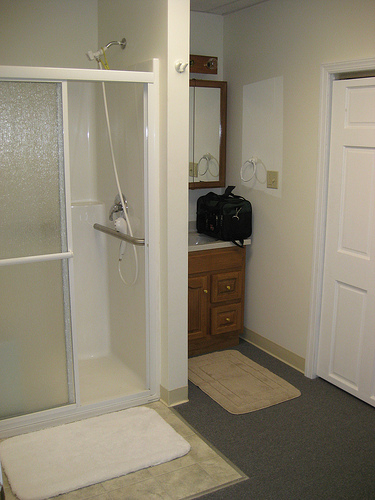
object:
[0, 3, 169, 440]
shower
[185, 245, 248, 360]
cabinets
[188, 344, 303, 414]
mat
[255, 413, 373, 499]
carpet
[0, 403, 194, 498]
bath mat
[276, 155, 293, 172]
ground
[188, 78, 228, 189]
mirror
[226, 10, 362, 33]
wall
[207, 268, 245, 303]
drawer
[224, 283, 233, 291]
knob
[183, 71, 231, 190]
cabinet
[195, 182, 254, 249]
black bag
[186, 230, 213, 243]
sink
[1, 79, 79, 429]
sliding door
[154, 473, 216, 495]
tile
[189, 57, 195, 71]
lightbulbs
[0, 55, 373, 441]
frame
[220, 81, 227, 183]
border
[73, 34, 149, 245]
shower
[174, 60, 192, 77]
towel hanger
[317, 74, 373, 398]
door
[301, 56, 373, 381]
door frame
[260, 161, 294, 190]
switch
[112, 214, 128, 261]
shower head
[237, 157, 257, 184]
towel rod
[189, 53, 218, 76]
fixture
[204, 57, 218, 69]
light bulb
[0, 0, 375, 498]
bathroom